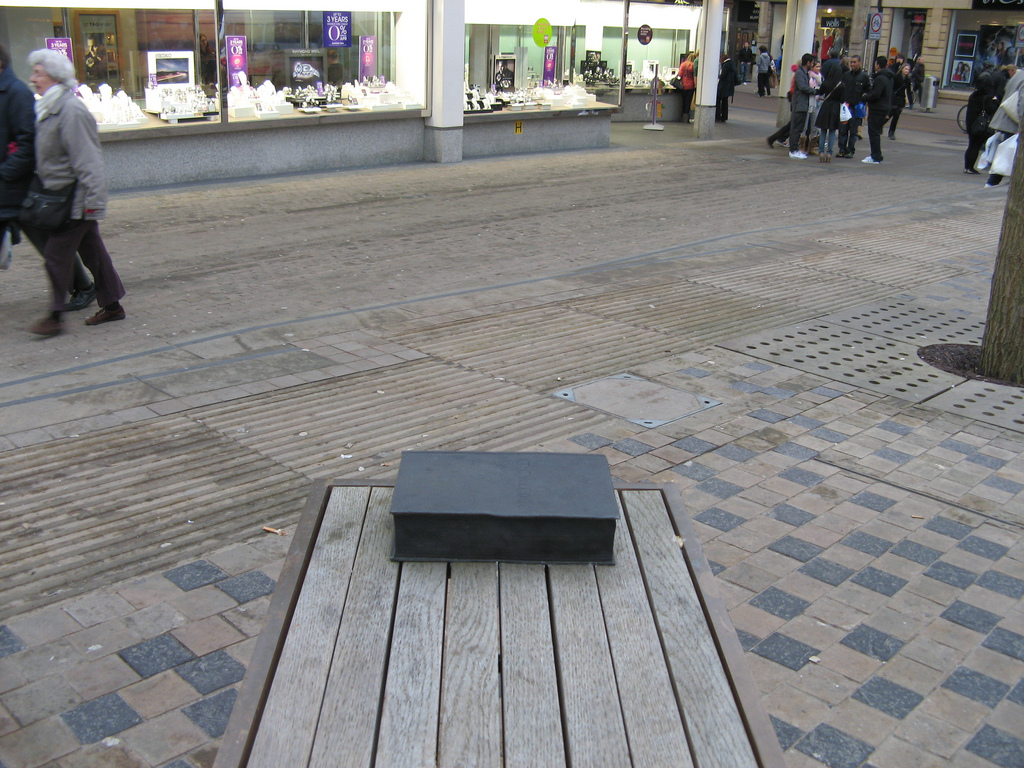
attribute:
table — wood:
[188, 458, 783, 760]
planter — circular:
[912, 337, 1021, 388]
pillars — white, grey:
[691, 7, 824, 154]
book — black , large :
[378, 434, 628, 577]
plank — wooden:
[225, 464, 772, 766]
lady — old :
[14, 39, 133, 335]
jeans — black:
[865, 105, 891, 160]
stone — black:
[108, 625, 204, 683]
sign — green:
[526, 14, 558, 50]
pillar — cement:
[422, 4, 470, 169]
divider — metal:
[211, 4, 235, 135]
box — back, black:
[383, 440, 628, 574]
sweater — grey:
[27, 87, 120, 228]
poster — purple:
[318, 14, 363, 54]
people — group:
[760, 40, 932, 174]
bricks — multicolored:
[271, 285, 838, 448]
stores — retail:
[94, 14, 845, 214]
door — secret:
[285, 399, 715, 763]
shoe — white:
[840, 141, 893, 181]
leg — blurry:
[29, 186, 79, 334]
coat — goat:
[28, 85, 106, 224]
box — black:
[374, 425, 634, 581]